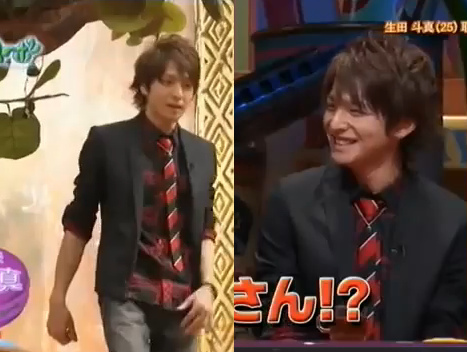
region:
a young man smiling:
[241, 16, 462, 233]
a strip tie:
[163, 143, 187, 271]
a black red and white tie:
[165, 140, 185, 276]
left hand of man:
[166, 280, 235, 321]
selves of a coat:
[35, 164, 107, 244]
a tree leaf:
[0, 74, 62, 167]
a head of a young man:
[311, 32, 449, 174]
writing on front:
[244, 272, 394, 334]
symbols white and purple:
[1, 240, 42, 326]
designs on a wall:
[199, 21, 233, 123]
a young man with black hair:
[303, 28, 438, 170]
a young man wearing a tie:
[132, 19, 200, 240]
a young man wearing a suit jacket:
[102, 37, 215, 230]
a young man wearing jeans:
[76, 19, 196, 350]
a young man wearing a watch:
[191, 244, 223, 332]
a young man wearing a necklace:
[269, 45, 449, 272]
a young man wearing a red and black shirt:
[112, 41, 204, 275]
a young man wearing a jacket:
[97, 33, 205, 241]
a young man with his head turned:
[260, 41, 440, 196]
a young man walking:
[37, 24, 213, 350]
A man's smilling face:
[317, 30, 419, 205]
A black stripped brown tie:
[159, 133, 180, 264]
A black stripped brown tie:
[365, 197, 387, 339]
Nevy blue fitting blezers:
[67, 123, 211, 285]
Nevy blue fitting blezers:
[261, 169, 457, 335]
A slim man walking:
[96, 39, 218, 345]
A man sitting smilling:
[267, 39, 456, 350]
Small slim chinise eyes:
[323, 99, 378, 117]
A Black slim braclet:
[196, 279, 222, 299]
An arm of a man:
[50, 131, 94, 340]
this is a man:
[35, 30, 220, 350]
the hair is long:
[148, 40, 190, 62]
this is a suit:
[87, 139, 136, 191]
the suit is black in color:
[88, 136, 131, 192]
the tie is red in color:
[163, 155, 178, 189]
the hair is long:
[355, 50, 417, 89]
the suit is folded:
[61, 194, 91, 226]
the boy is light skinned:
[369, 137, 385, 161]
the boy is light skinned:
[363, 123, 379, 144]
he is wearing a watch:
[209, 281, 217, 293]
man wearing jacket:
[44, 22, 221, 349]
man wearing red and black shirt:
[118, 124, 206, 326]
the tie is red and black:
[138, 132, 192, 276]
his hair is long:
[109, 37, 225, 124]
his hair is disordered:
[88, 23, 246, 143]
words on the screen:
[206, 267, 389, 321]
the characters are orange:
[200, 266, 371, 326]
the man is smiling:
[221, 22, 465, 344]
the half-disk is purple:
[0, 246, 30, 338]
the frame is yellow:
[192, 3, 243, 341]